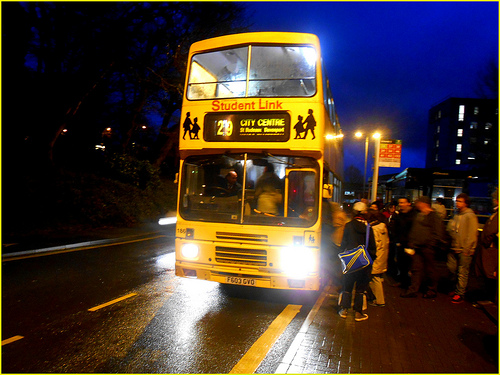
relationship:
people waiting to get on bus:
[325, 197, 492, 285] [161, 27, 366, 271]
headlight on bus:
[181, 243, 199, 259] [165, 27, 344, 316]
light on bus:
[300, 47, 320, 67] [165, 27, 344, 316]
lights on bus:
[343, 124, 389, 154] [165, 27, 344, 316]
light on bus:
[225, 71, 257, 95] [165, 27, 344, 316]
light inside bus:
[294, 43, 320, 79] [165, 27, 344, 316]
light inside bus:
[217, 65, 259, 94] [165, 27, 344, 316]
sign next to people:
[371, 137, 401, 207] [321, 190, 498, 320]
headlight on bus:
[175, 235, 203, 265] [171, 30, 323, 326]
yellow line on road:
[235, 304, 290, 371] [24, 241, 235, 373]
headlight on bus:
[181, 243, 199, 259] [198, 30, 408, 305]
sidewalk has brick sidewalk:
[347, 274, 494, 367] [324, 320, 419, 374]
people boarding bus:
[321, 180, 482, 314] [165, 27, 344, 316]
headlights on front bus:
[172, 236, 314, 289] [178, 34, 325, 289]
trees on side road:
[10, 5, 258, 242] [24, 241, 235, 373]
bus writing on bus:
[212, 99, 283, 111] [176, 27, 359, 314]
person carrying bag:
[335, 198, 375, 322] [340, 246, 375, 270]